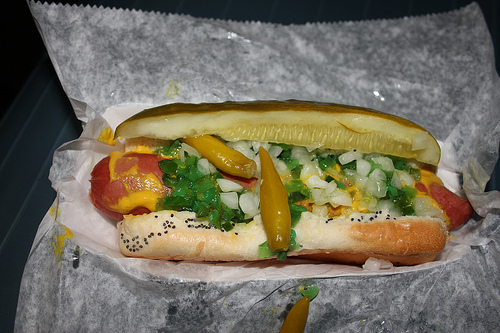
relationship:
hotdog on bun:
[90, 148, 475, 232] [111, 209, 446, 266]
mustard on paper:
[52, 130, 158, 255] [14, 1, 499, 330]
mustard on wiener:
[52, 130, 158, 255] [90, 146, 474, 233]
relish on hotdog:
[168, 157, 241, 213] [90, 148, 475, 232]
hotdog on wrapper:
[90, 148, 475, 232] [14, 1, 498, 331]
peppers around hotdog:
[180, 134, 295, 254] [90, 148, 475, 232]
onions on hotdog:
[308, 175, 352, 208] [90, 148, 475, 232]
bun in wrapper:
[111, 209, 446, 266] [14, 1, 498, 331]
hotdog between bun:
[90, 148, 475, 232] [111, 209, 446, 266]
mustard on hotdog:
[52, 130, 158, 255] [90, 148, 475, 232]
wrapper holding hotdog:
[14, 1, 498, 331] [90, 148, 475, 232]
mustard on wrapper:
[52, 130, 158, 255] [14, 1, 498, 331]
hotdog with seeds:
[90, 148, 475, 232] [114, 214, 186, 254]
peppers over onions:
[180, 134, 295, 254] [308, 175, 352, 208]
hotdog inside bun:
[90, 148, 475, 232] [111, 209, 446, 266]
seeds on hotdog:
[114, 214, 186, 254] [90, 148, 475, 232]